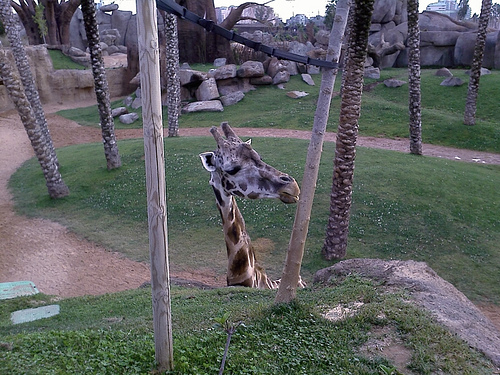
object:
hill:
[1, 258, 500, 375]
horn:
[208, 126, 227, 150]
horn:
[220, 122, 238, 141]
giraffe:
[197, 122, 308, 290]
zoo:
[0, 0, 500, 375]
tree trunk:
[271, 0, 349, 307]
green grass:
[382, 158, 482, 249]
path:
[1, 97, 139, 309]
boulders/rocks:
[176, 39, 314, 113]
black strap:
[153, 0, 339, 70]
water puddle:
[453, 156, 486, 165]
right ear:
[198, 151, 218, 173]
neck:
[209, 181, 260, 288]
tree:
[15, 0, 85, 47]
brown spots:
[222, 230, 255, 281]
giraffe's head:
[198, 121, 302, 206]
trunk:
[320, 0, 375, 263]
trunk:
[165, 11, 181, 138]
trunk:
[79, 0, 125, 170]